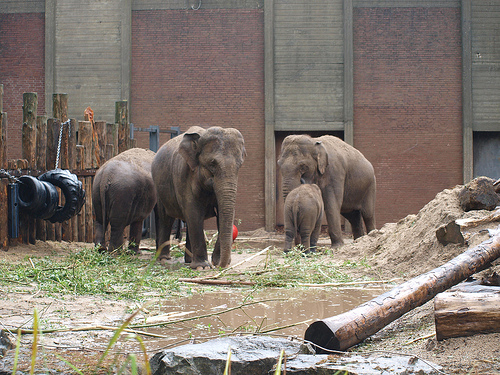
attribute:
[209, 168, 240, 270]
trunk — long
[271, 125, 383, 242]
elephant — older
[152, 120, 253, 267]
elephant — older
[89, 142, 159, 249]
elephant — large, older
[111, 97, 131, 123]
post — wood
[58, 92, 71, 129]
post — wood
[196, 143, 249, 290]
trunk — elephants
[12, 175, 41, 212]
black tire — thick, hanging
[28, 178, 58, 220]
black tire — thick, hanging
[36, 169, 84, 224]
black tire — thick, hanging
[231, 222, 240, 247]
red object — small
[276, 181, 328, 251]
elephant — hanging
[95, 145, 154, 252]
elephant — hanging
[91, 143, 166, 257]
elephant — large, brown, black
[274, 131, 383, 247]
elephant — large, brown, black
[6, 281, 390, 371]
puddle — stagnant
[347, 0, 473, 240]
wall — red, black, brick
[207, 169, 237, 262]
trunk — long, elephant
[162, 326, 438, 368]
rocks — large, wet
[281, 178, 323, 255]
elephant — baby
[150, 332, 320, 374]
rocks — large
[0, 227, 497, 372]
ground — wet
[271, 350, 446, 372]
rocks — large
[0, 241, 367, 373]
grass — long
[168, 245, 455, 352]
water — brown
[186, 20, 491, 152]
building — brick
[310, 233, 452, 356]
log — thick, brown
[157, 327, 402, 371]
rock — wet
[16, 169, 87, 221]
tire — three, black, rubber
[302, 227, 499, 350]
log — long, brown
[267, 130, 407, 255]
elephant — adult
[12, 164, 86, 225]
tires — three, large, black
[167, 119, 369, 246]
elephants — small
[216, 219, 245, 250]
ball — large, red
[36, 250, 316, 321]
grass — patchy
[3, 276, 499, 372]
puddle — muddy, water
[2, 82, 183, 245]
fence — wooden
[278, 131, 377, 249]
elephant — large, hanging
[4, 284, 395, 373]
water — brown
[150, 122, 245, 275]
elephant — large, hanging, brown, black